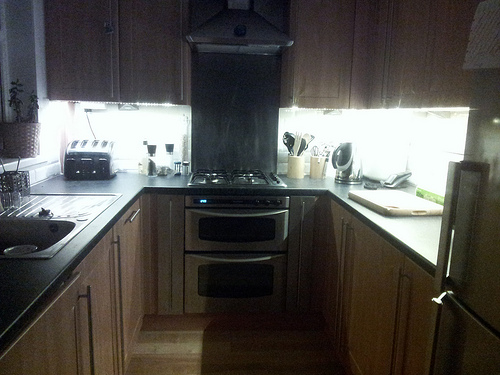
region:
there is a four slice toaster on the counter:
[62, 118, 114, 183]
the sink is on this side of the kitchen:
[0, 171, 95, 258]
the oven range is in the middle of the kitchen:
[191, 151, 291, 317]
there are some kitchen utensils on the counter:
[281, 123, 329, 183]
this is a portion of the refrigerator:
[426, 93, 494, 370]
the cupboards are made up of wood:
[33, 222, 413, 367]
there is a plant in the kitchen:
[6, 57, 61, 163]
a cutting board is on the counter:
[348, 165, 434, 236]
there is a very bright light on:
[336, 108, 438, 148]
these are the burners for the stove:
[194, 163, 271, 187]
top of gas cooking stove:
[188, 166, 268, 190]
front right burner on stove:
[228, 173, 267, 185]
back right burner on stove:
[228, 169, 263, 175]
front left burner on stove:
[191, 174, 226, 184]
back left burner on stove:
[192, 167, 226, 174]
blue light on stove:
[195, 198, 207, 203]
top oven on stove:
[185, 205, 290, 257]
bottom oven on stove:
[181, 251, 288, 309]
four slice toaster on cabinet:
[63, 132, 110, 179]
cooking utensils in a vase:
[278, 125, 315, 181]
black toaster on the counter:
[65, 143, 115, 182]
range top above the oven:
[187, 168, 284, 190]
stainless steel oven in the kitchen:
[186, 197, 287, 306]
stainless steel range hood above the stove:
[192, 9, 291, 54]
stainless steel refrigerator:
[426, 69, 497, 369]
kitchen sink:
[0, 217, 75, 263]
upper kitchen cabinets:
[47, 5, 477, 108]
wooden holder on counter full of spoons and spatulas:
[285, 131, 308, 176]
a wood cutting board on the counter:
[350, 188, 440, 215]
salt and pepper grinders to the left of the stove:
[148, 144, 175, 176]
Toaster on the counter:
[66, 137, 118, 182]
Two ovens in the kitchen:
[187, 195, 290, 323]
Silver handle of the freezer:
[436, 158, 459, 297]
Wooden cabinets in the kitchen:
[297, 0, 348, 106]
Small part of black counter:
[413, 224, 429, 246]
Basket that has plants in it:
[7, 120, 42, 155]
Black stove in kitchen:
[196, 168, 277, 188]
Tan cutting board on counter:
[353, 190, 443, 214]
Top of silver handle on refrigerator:
[423, 298, 446, 348]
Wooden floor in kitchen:
[153, 325, 203, 369]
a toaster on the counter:
[62, 131, 157, 210]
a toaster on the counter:
[57, 127, 143, 186]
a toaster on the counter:
[49, 122, 172, 207]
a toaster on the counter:
[48, 119, 168, 200]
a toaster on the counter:
[53, 122, 119, 177]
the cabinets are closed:
[273, 120, 314, 180]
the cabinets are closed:
[111, 213, 177, 368]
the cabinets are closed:
[296, 190, 426, 370]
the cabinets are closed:
[71, 12, 157, 97]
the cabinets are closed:
[294, 24, 447, 121]